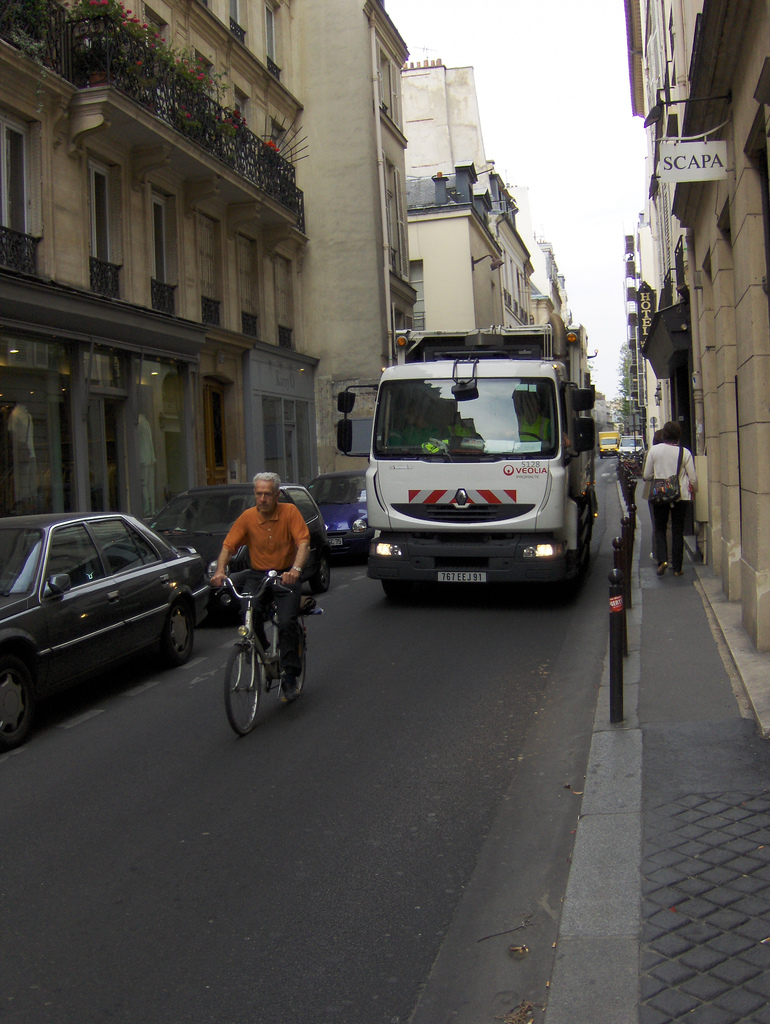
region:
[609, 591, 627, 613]
the red sticker on the black pole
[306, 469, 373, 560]
the purple car next to the truck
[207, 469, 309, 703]
the man on the bike is wearing an orange shirt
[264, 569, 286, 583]
the silver bell on the bike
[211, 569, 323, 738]
the bike is in front of the white truck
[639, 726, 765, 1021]
the dark gray sidewalk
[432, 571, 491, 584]
the white license plate on the white truck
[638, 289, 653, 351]
the black and gold hotel sign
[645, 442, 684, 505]
the woman in white has a black purse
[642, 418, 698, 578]
the woman is wearing a white shirt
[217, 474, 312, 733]
man riding a bicycle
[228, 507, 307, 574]
man on bicycle's orange shirt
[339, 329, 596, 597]
white truck behind man on bicycle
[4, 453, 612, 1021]
small, one-way street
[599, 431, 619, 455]
yellow box truck in distance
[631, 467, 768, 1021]
small sidewalk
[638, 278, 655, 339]
black hotel sign on right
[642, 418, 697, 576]
woman with white shirt and dark purse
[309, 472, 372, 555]
little blue car on left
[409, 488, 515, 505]
red and white stripes on front of truck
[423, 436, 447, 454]
Reflective jacket behind the windshield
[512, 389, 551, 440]
Driver wearing reflective jacket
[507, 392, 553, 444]
Driver visible through the windshield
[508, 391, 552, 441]
Driver of truck behind the wheel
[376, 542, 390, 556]
The light of the truck is shining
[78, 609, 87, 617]
Reflection of vehicle light on the side of the car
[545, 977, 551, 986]
A cigarette stub on the road side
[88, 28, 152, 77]
A balcony filled with flowers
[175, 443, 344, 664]
man on a bike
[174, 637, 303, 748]
front tire of bike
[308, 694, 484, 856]
street next to bike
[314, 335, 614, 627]
front of the truck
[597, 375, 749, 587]
woman walking on sidewalk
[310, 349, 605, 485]
front window of the truck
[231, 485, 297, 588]
man is wearing a shirt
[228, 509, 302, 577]
shirt is orange in color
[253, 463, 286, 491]
man has hair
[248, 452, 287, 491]
hair is grey in color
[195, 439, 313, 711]
man is riding a bike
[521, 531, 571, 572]
truck has headlights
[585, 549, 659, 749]
pole on side of street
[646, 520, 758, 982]
sidewalk is made of brick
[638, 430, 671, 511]
woman is carrying a bag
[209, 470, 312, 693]
Grey haired man in an orange shirt.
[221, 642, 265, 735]
Front black bicycle wheel.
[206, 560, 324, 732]
A black and silver bicycle.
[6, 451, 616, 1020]
A paved dark grey road.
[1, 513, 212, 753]
A grey four door car by a man in orange.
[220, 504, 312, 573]
Orange shirt on a man.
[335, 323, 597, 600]
A large white and grey truck with headlights on.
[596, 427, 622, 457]
Yellow box truck in the distance.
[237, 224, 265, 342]
A window on a building.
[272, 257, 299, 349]
A window on a building.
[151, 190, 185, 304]
A window on a building.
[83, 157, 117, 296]
A window on a building.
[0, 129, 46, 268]
A window on a building.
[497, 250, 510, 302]
A window on a building.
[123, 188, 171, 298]
a window on the building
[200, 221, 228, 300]
a window on the building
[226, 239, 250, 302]
a window on the building